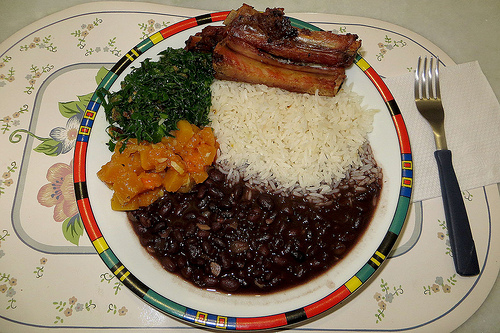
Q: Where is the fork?
A: On right.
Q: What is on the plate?
A: Food.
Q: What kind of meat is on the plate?
A: Spare ribs.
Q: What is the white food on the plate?
A: Rice.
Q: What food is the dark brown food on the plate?
A: Beans.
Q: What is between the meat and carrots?
A: Greens.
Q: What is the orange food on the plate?
A: Sweet potatoes.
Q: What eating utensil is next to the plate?
A: A fork.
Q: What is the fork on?
A: A napkin.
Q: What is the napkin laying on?
A: A placemat.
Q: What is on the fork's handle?
A: Plastic.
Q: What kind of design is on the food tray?
A: Floral.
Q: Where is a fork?
A: To the right of the plate.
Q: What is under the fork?
A: A napkin.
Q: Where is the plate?
A: On a placemat.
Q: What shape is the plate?
A: Round.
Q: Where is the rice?
A: On plate.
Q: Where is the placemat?
A: On table.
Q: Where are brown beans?
A: On the plate.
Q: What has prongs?
A: The fork.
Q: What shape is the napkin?
A: Square.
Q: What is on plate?
A: Food.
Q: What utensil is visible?
A: Fork.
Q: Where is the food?
A: On circle plate.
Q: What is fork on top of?
A: White napkin.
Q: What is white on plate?
A: Rice.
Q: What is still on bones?
A: The meat.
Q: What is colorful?
A: Trim of plate.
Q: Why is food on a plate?
A: To be eaten.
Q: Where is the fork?
A: On a napkin.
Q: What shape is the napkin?
A: Square.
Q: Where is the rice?
A: On plate.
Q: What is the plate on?
A: A placemat.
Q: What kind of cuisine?
A: Cuban.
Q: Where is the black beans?
A: With the rice.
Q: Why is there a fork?
A: For eating.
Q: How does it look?
A: Delicious.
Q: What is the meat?
A: Pork.